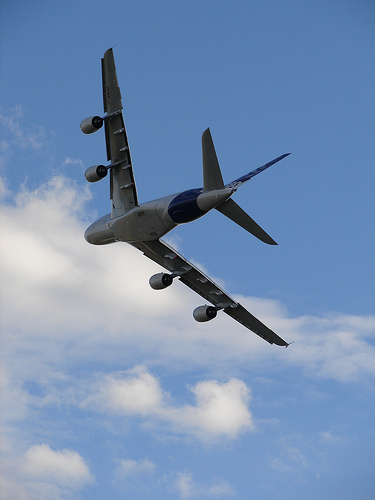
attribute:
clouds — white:
[50, 411, 86, 445]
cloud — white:
[159, 373, 259, 444]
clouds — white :
[1, 94, 374, 497]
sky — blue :
[0, 24, 374, 407]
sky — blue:
[210, 10, 372, 105]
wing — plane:
[129, 239, 289, 347]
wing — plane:
[101, 48, 136, 215]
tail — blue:
[165, 185, 240, 227]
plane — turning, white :
[85, 46, 295, 345]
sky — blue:
[255, 52, 331, 146]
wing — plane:
[66, 53, 142, 182]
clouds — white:
[291, 180, 352, 268]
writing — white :
[227, 179, 238, 189]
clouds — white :
[2, 189, 374, 492]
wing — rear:
[196, 123, 224, 189]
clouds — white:
[222, 383, 262, 438]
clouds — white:
[1, 177, 373, 443]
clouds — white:
[3, 178, 255, 445]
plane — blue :
[86, 34, 354, 336]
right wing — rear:
[219, 201, 280, 254]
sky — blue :
[257, 56, 337, 84]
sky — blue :
[23, 35, 334, 302]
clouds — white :
[11, 268, 133, 333]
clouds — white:
[198, 400, 243, 431]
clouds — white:
[20, 241, 92, 316]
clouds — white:
[111, 376, 153, 414]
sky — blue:
[6, 0, 370, 497]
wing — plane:
[97, 46, 139, 226]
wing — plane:
[138, 234, 296, 350]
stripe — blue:
[169, 186, 205, 222]